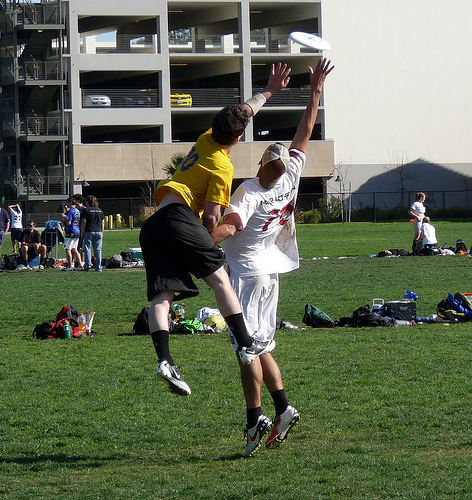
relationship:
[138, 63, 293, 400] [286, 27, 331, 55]
man jumping for frisbee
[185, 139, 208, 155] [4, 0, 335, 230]
yellow car on second floor of parking garage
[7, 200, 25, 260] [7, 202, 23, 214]
person on back of ir head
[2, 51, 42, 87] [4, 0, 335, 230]
metal stairs attached to parking garage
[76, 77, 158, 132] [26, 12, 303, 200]
car parked in garage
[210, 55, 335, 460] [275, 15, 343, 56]
man playing frisbee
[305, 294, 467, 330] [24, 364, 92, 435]
bags on ground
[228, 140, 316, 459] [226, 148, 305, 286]
man in white shirt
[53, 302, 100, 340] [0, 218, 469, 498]
orange backpack in open field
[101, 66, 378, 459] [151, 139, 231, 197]
man in shirt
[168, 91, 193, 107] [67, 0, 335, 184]
yellow car in parking garage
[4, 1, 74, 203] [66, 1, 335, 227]
stairs of parking garage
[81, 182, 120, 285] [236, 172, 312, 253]
person in shirt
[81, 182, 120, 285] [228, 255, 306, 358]
person in shorts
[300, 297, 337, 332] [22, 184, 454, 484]
bag on ground